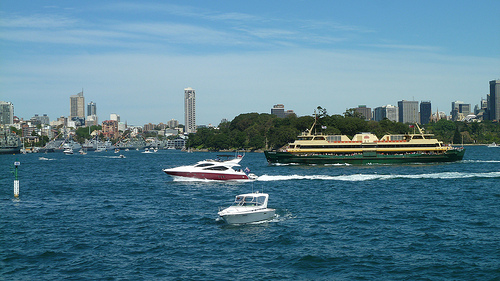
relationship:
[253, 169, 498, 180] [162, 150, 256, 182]
wake from boat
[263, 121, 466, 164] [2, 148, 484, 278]
boat on water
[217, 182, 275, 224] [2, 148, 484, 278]
boat on water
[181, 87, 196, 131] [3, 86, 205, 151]
building in city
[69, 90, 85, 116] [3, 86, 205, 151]
building in city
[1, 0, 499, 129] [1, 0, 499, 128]
clouds in sky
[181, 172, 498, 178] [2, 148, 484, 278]
wave in water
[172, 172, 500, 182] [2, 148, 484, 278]
wave in water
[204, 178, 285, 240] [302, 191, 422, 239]
boat driving in water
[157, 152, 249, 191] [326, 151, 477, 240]
boat in water